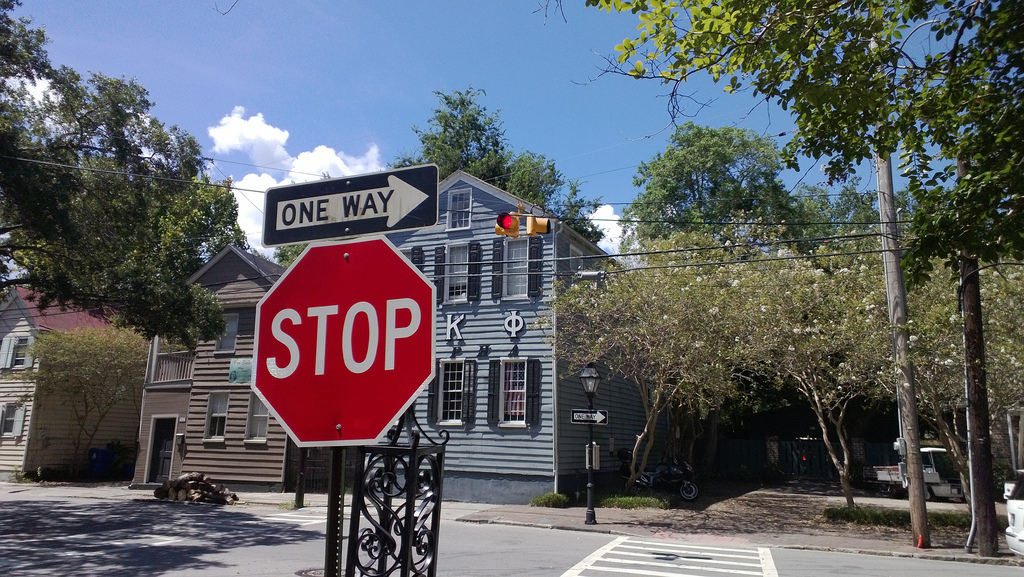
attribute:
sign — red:
[265, 226, 431, 442]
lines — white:
[578, 522, 779, 570]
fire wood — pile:
[168, 462, 216, 501]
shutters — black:
[434, 243, 482, 304]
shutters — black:
[489, 357, 540, 430]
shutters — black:
[429, 357, 477, 428]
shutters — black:
[492, 238, 544, 297]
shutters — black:
[407, 244, 423, 267]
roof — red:
[7, 281, 124, 329]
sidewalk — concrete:
[460, 481, 1020, 561]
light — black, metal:
[581, 363, 601, 523]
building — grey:
[363, 170, 684, 502]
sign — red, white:
[251, 232, 438, 445]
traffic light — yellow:
[491, 205, 518, 231]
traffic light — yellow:
[519, 213, 558, 237]